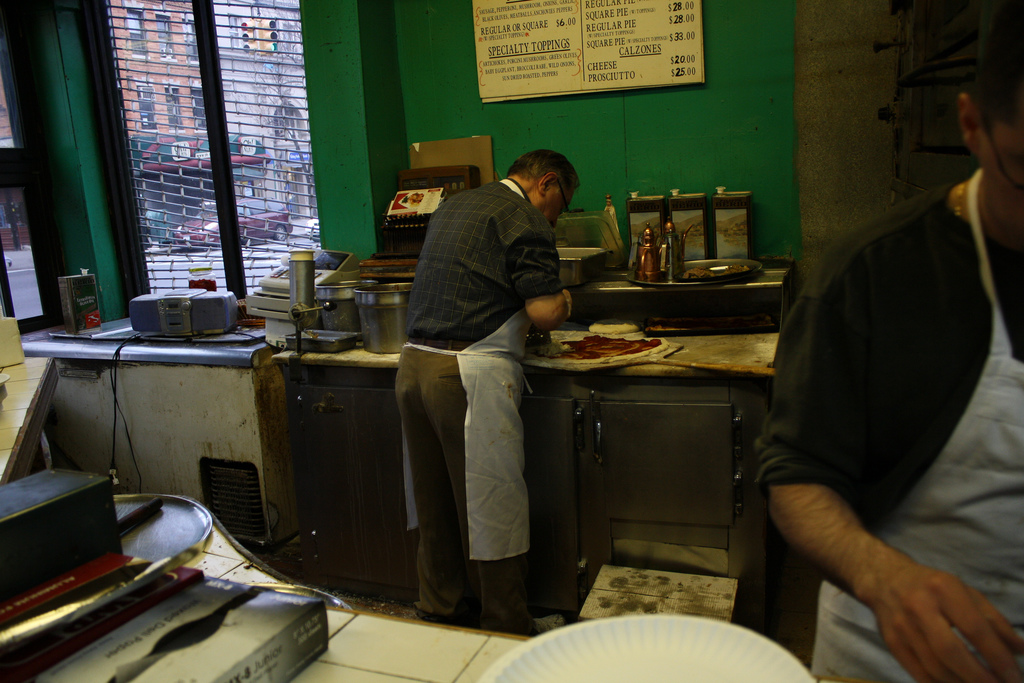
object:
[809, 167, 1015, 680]
apron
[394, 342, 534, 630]
pants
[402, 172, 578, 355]
gray shirt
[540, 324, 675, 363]
pizza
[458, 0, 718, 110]
menu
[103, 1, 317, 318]
window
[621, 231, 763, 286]
tray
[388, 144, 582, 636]
chef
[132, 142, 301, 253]
red car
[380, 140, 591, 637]
man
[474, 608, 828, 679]
paper plate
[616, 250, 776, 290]
serving platter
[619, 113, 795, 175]
wall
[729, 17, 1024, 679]
man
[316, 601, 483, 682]
white tiles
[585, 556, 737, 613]
white tiles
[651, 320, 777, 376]
counter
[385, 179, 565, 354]
shirt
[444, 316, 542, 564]
apron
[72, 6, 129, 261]
framed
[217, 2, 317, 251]
blinds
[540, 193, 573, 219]
glasses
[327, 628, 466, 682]
floor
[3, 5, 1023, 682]
room